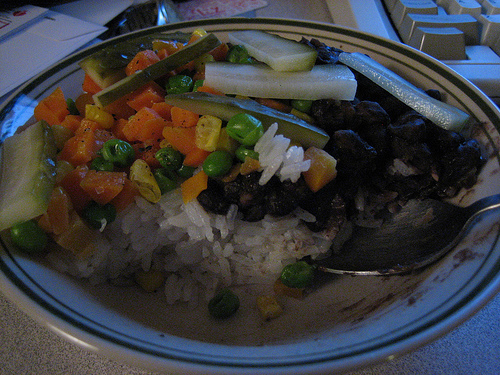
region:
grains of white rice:
[254, 121, 312, 190]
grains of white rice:
[79, 191, 328, 314]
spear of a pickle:
[199, 58, 360, 100]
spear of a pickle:
[222, 22, 319, 72]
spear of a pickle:
[87, 31, 224, 111]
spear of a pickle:
[335, 42, 477, 135]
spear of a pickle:
[0, 114, 60, 241]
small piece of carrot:
[75, 168, 130, 206]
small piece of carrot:
[120, 102, 160, 147]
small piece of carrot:
[62, 112, 110, 167]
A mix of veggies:
[81, 109, 216, 199]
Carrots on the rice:
[60, 109, 212, 203]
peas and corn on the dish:
[181, 107, 270, 172]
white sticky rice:
[159, 224, 291, 279]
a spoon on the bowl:
[335, 167, 486, 286]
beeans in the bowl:
[316, 82, 461, 191]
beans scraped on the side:
[370, 264, 438, 331]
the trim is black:
[57, 307, 477, 374]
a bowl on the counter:
[1, 299, 474, 371]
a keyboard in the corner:
[322, 3, 499, 88]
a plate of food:
[37, 13, 447, 364]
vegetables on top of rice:
[22, 10, 405, 346]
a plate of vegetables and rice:
[32, 21, 489, 325]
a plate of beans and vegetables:
[36, 0, 491, 342]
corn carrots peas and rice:
[25, 18, 415, 359]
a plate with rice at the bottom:
[73, 23, 497, 280]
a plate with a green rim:
[32, 28, 425, 370]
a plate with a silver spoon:
[16, 34, 443, 369]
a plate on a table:
[51, 42, 499, 316]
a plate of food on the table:
[28, 20, 490, 362]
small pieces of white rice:
[116, 138, 338, 318]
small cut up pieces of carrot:
[60, 87, 355, 198]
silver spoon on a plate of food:
[294, 170, 478, 295]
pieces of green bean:
[123, 74, 351, 259]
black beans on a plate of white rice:
[161, 26, 498, 325]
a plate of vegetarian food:
[30, 42, 480, 362]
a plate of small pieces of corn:
[108, 154, 318, 339]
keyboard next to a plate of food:
[333, 2, 499, 93]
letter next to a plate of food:
[3, 1, 137, 186]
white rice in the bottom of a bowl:
[129, 198, 266, 289]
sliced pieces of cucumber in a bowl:
[143, 36, 457, 153]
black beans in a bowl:
[207, 178, 319, 215]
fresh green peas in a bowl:
[218, 112, 275, 163]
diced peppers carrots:
[122, 111, 167, 136]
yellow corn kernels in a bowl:
[190, 113, 229, 151]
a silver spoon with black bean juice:
[344, 194, 456, 274]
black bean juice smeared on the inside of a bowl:
[348, 269, 465, 318]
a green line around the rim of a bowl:
[49, 298, 120, 336]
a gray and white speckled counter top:
[6, 326, 53, 367]